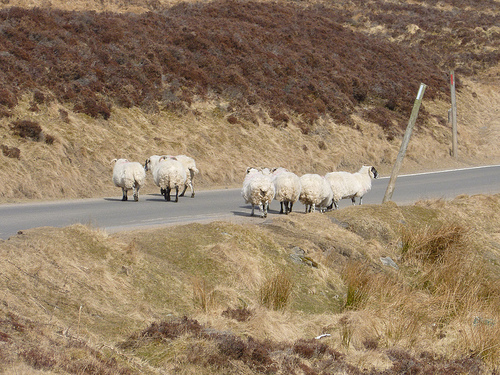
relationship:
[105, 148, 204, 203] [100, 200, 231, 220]
sheep on left of road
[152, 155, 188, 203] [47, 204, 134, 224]
sheep on left of road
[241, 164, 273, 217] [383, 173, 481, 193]
sheep on left of road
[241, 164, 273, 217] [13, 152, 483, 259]
sheep on left of road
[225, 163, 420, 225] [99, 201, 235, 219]
sheep turn left on road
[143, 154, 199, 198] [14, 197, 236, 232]
sheep turn left on road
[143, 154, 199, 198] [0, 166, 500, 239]
sheep turn left on road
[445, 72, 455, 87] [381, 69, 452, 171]
paint on pole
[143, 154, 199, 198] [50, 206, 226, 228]
sheep crossing road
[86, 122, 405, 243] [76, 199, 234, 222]
sheep on road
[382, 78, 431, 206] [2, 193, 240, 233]
wood pole beside road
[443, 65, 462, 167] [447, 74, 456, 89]
pole with sticker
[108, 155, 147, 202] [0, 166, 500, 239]
sheep on road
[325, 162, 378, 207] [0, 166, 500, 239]
sheep on road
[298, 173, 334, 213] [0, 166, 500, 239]
sheep on road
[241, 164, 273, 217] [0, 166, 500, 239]
sheep on road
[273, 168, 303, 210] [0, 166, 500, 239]
sheep on road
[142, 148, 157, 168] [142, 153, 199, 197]
head of sheep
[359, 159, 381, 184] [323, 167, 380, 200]
head of sheep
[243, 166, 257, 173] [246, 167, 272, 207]
head of sheep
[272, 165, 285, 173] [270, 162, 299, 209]
head of sheep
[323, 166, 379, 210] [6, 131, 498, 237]
sheep crossing street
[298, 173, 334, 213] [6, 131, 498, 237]
sheep crossing street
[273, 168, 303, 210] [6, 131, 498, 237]
sheep crossing street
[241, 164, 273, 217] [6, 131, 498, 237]
sheep crossing street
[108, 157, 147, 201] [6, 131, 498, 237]
sheep crossing street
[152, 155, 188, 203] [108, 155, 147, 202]
sheep walking with sheep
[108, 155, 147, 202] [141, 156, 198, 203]
sheep walking with sheep